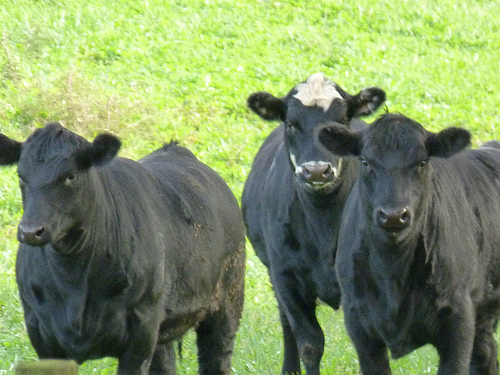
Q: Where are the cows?
A: On the grass.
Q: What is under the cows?
A: Grass.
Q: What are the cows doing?
A: Standing.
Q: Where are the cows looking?
A: At the camera.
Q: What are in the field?
A: Cows.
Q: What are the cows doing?
A: Looking at the camera.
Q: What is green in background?
A: Grass.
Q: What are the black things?
A: Cows.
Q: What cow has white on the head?
A: The middle one.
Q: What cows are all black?
A: The ones on the ends.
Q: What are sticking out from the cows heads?
A: Ears.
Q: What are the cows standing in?
A: A green field.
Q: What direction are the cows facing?
A: Forward.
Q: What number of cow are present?
A: 3.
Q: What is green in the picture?
A: Grass.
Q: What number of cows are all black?
A: 2.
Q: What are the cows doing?
A: Staring.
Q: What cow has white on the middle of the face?
A: Middle.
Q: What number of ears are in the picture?
A: 6.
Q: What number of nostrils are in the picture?
A: 6.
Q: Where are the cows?
A: Farm.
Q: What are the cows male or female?
A: Female.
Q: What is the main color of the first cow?
A: Black.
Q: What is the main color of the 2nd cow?
A: Black.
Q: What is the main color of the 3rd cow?
A: Black.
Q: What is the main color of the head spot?
A: White.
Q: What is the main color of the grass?
A: Green.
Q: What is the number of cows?
A: 3.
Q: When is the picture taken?
A: Daytime.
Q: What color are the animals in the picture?
A: Black.